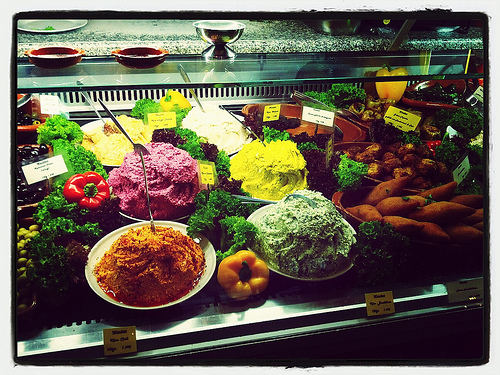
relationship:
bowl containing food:
[80, 220, 217, 314] [93, 225, 203, 308]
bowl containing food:
[243, 203, 358, 282] [253, 193, 356, 278]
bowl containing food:
[100, 157, 206, 223] [96, 139, 212, 224]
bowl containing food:
[210, 148, 316, 206] [214, 133, 312, 204]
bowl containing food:
[71, 105, 164, 171] [78, 109, 158, 169]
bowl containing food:
[172, 95, 254, 159] [175, 99, 252, 158]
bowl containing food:
[324, 178, 456, 250] [342, 170, 488, 245]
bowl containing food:
[319, 133, 461, 198] [334, 135, 448, 190]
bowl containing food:
[238, 97, 366, 147] [254, 102, 359, 148]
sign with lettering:
[17, 151, 69, 183] [392, 110, 408, 122]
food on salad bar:
[107, 142, 207, 219] [16, 20, 489, 364]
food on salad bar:
[250, 189, 356, 277] [16, 57, 486, 359]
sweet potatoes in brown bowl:
[346, 173, 484, 245] [328, 180, 480, 260]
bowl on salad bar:
[112, 45, 170, 70] [16, 57, 486, 359]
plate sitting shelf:
[16, 17, 91, 34] [23, 69, 301, 89]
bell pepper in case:
[63, 171, 110, 210] [18, 56, 488, 366]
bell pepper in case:
[59, 166, 109, 208] [24, 61, 484, 342]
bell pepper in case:
[369, 60, 405, 100] [24, 61, 484, 342]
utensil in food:
[138, 149, 155, 234] [99, 224, 200, 301]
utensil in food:
[92, 106, 177, 246] [85, 91, 297, 295]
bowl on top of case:
[193, 18, 241, 59] [20, 56, 473, 75]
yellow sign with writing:
[263, 104, 282, 122] [248, 98, 298, 137]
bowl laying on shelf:
[24, 46, 86, 69] [15, 53, 380, 89]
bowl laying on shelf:
[111, 47, 169, 69] [15, 53, 380, 89]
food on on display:
[126, 242, 183, 272] [84, 95, 462, 313]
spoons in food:
[93, 89, 155, 156] [59, 95, 472, 307]